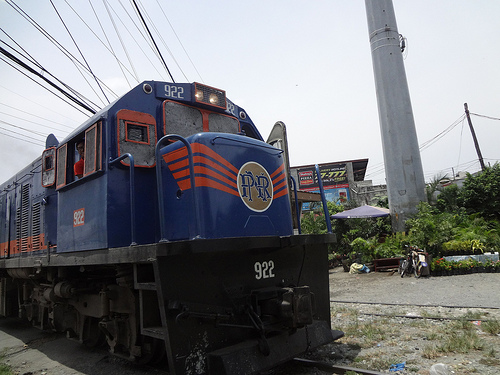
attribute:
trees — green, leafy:
[435, 160, 498, 210]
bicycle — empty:
[396, 242, 426, 283]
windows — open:
[56, 128, 96, 188]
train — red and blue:
[33, 83, 406, 368]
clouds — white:
[257, 26, 327, 73]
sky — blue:
[4, 4, 497, 178]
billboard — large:
[293, 157, 368, 190]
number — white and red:
[239, 253, 292, 296]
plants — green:
[340, 190, 499, 267]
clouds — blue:
[2, 1, 498, 183]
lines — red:
[162, 141, 297, 203]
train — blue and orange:
[1, 72, 354, 373]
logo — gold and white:
[223, 149, 275, 217]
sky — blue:
[192, 2, 362, 81]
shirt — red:
[72, 158, 84, 176]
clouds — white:
[216, 26, 374, 133]